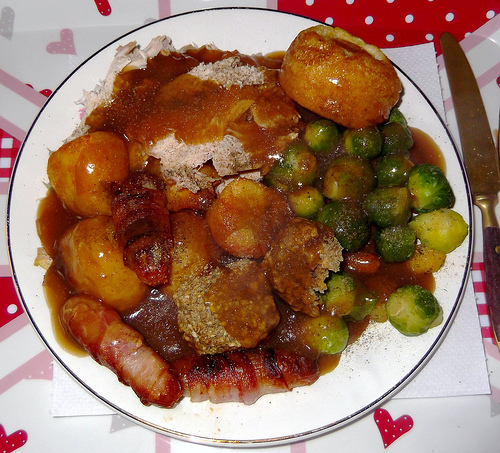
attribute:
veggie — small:
[302, 315, 349, 355]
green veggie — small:
[321, 271, 356, 318]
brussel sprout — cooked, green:
[387, 282, 444, 339]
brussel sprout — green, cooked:
[409, 161, 456, 214]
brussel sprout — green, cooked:
[364, 182, 416, 227]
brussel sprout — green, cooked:
[376, 221, 418, 263]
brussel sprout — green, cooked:
[313, 200, 370, 251]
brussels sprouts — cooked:
[272, 126, 460, 233]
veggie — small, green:
[303, 130, 458, 262]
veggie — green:
[381, 229, 419, 257]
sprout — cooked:
[384, 288, 449, 334]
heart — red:
[368, 406, 418, 448]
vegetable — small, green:
[361, 183, 414, 227]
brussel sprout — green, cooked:
[407, 208, 468, 249]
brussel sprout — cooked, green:
[326, 151, 380, 196]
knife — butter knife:
[419, 36, 499, 346]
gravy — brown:
[37, 190, 84, 259]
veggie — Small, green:
[382, 282, 444, 339]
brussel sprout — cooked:
[306, 116, 335, 153]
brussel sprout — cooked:
[343, 119, 380, 156]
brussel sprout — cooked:
[379, 110, 414, 157]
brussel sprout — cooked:
[410, 204, 469, 259]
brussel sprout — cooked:
[360, 184, 415, 227]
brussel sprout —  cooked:
[290, 185, 324, 215]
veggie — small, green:
[298, 115, 343, 154]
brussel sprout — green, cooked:
[377, 286, 436, 331]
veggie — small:
[344, 154, 378, 192]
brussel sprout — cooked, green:
[321, 268, 358, 319]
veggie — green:
[386, 284, 443, 336]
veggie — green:
[319, 154, 376, 203]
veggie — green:
[317, 200, 370, 254]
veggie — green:
[375, 223, 417, 262]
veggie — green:
[406, 162, 456, 214]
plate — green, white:
[6, 7, 473, 447]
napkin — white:
[445, 352, 477, 392]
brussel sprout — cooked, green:
[362, 181, 415, 230]